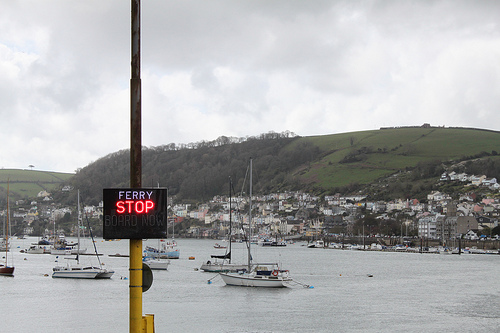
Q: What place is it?
A: It is an ocean.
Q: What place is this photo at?
A: It is at the ocean.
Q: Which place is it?
A: It is an ocean.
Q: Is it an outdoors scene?
A: Yes, it is outdoors.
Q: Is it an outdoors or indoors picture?
A: It is outdoors.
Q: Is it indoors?
A: No, it is outdoors.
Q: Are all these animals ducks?
A: Yes, all the animals are ducks.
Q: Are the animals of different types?
A: No, all the animals are ducks.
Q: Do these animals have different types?
A: No, all the animals are ducks.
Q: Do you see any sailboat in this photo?
A: Yes, there is a sailboat.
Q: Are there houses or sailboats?
A: Yes, there is a sailboat.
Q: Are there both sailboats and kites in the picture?
A: No, there is a sailboat but no kites.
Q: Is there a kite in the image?
A: No, there are no kites.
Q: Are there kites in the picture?
A: No, there are no kites.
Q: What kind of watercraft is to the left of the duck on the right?
A: The watercraft is a sailboat.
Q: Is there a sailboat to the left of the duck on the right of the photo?
A: Yes, there is a sailboat to the left of the duck.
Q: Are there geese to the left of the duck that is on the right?
A: No, there is a sailboat to the left of the duck.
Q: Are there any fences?
A: No, there are no fences.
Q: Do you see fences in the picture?
A: No, there are no fences.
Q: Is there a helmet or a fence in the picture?
A: No, there are no fences or helmets.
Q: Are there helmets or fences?
A: No, there are no fences or helmets.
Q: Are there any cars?
A: No, there are no cars.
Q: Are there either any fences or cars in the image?
A: No, there are no cars or fences.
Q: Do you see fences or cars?
A: No, there are no cars or fences.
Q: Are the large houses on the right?
A: Yes, the houses are on the right of the image.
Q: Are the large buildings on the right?
A: Yes, the houses are on the right of the image.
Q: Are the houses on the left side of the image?
A: No, the houses are on the right of the image.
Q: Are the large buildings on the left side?
A: No, the houses are on the right of the image.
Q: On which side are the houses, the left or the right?
A: The houses are on the right of the image.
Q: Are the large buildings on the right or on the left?
A: The houses are on the right of the image.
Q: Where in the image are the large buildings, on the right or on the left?
A: The houses are on the right of the image.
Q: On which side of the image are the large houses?
A: The houses are on the right of the image.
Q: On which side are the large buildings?
A: The houses are on the right of the image.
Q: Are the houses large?
A: Yes, the houses are large.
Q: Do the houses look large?
A: Yes, the houses are large.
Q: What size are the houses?
A: The houses are large.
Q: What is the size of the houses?
A: The houses are large.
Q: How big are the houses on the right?
A: The houses are large.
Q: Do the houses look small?
A: No, the houses are large.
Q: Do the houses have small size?
A: No, the houses are large.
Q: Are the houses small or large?
A: The houses are large.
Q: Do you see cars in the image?
A: No, there are no cars.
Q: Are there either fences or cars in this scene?
A: No, there are no cars or fences.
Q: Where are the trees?
A: The trees are on the hill.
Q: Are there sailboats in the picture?
A: Yes, there is a sailboat.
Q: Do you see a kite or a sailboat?
A: Yes, there is a sailboat.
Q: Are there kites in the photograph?
A: No, there are no kites.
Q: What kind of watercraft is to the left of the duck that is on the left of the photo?
A: The watercraft is a sailboat.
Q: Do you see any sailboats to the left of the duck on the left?
A: Yes, there is a sailboat to the left of the duck.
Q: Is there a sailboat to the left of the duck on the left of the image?
A: Yes, there is a sailboat to the left of the duck.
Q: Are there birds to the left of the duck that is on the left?
A: No, there is a sailboat to the left of the duck.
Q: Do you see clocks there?
A: No, there are no clocks.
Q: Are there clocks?
A: No, there are no clocks.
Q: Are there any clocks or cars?
A: No, there are no clocks or cars.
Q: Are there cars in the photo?
A: No, there are no cars.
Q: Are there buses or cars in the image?
A: No, there are no cars or buses.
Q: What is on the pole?
A: The sign is on the pole.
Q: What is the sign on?
A: The sign is on the pole.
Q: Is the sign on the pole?
A: Yes, the sign is on the pole.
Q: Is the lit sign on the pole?
A: Yes, the sign is on the pole.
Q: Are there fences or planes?
A: No, there are no fences or planes.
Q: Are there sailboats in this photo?
A: Yes, there is a sailboat.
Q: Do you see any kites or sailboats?
A: Yes, there is a sailboat.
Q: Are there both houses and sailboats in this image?
A: Yes, there are both a sailboat and a house.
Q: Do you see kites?
A: No, there are no kites.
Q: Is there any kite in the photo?
A: No, there are no kites.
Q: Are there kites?
A: No, there are no kites.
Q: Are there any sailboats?
A: Yes, there is a sailboat.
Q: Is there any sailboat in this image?
A: Yes, there is a sailboat.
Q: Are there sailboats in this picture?
A: Yes, there is a sailboat.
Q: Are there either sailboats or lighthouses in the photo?
A: Yes, there is a sailboat.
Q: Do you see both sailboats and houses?
A: Yes, there are both a sailboat and a house.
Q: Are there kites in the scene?
A: No, there are no kites.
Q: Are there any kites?
A: No, there are no kites.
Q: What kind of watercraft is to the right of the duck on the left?
A: The watercraft is a sailboat.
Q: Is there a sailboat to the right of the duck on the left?
A: Yes, there is a sailboat to the right of the duck.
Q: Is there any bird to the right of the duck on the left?
A: No, there is a sailboat to the right of the duck.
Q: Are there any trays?
A: No, there are no trays.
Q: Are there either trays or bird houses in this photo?
A: No, there are no trays or bird houses.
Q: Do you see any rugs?
A: No, there are no rugs.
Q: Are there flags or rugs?
A: No, there are no rugs or flags.